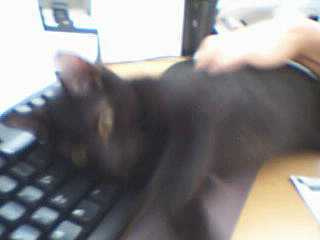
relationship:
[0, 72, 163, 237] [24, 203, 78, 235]
keyboard has buttons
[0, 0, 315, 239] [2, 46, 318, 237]
picture of black cat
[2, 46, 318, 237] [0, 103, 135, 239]
black cat laying on keyboard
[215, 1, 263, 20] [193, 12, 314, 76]
person has blurry hand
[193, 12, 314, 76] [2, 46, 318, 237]
blurry hand on black cat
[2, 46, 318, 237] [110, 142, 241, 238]
black cat stretching cat arms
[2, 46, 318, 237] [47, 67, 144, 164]
black cat has head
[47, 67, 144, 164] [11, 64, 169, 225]
head on keyboard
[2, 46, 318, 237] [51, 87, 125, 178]
black cat has eyes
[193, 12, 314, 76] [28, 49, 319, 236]
blurry hand petting cat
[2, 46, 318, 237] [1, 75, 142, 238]
black cat laying on keyboard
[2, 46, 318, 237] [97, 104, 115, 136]
black cat has eye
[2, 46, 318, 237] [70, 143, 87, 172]
black cat has eye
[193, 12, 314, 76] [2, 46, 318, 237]
blurry hand on a black cat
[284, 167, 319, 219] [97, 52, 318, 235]
paper on a desk